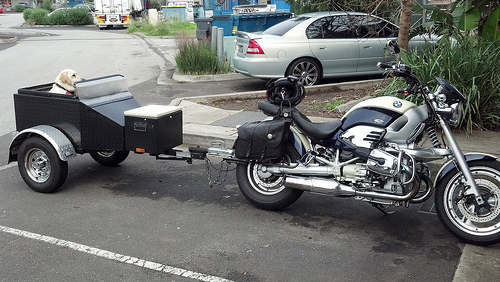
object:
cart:
[6, 73, 188, 193]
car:
[229, 9, 468, 88]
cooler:
[124, 103, 185, 152]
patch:
[173, 70, 215, 84]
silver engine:
[278, 146, 421, 206]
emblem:
[392, 101, 407, 108]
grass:
[379, 35, 499, 132]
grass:
[127, 17, 199, 35]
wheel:
[13, 130, 72, 194]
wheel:
[85, 143, 136, 169]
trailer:
[4, 70, 181, 193]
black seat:
[257, 100, 342, 141]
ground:
[0, 11, 500, 281]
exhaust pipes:
[264, 155, 438, 206]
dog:
[49, 67, 87, 97]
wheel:
[432, 155, 500, 247]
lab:
[41, 67, 80, 106]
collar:
[50, 80, 77, 95]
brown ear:
[58, 72, 67, 84]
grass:
[173, 43, 231, 77]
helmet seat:
[271, 87, 296, 127]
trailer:
[95, 1, 145, 30]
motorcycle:
[232, 60, 500, 246]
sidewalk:
[0, 131, 500, 281]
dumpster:
[206, 3, 294, 38]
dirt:
[207, 85, 377, 118]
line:
[0, 225, 237, 282]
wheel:
[236, 139, 309, 210]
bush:
[176, 35, 219, 77]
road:
[0, 12, 498, 281]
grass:
[22, 7, 95, 26]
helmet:
[263, 75, 305, 106]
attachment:
[7, 73, 183, 195]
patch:
[109, 229, 128, 239]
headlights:
[246, 39, 266, 57]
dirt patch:
[223, 95, 248, 106]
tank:
[326, 87, 435, 155]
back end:
[94, 0, 131, 30]